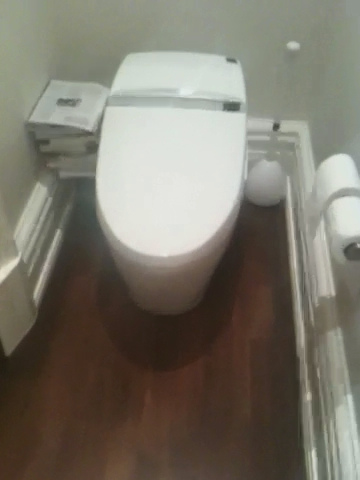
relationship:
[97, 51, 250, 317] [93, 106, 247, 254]
toliet has a lid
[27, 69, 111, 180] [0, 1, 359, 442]
newspaper on wall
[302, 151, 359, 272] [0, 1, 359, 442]
toliet paper on wall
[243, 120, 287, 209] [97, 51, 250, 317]
toilet bowl cleaner next to toliet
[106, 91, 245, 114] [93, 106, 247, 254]
stripe on lid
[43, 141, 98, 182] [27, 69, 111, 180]
books under newspaper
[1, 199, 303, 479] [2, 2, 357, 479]
floor in bathroom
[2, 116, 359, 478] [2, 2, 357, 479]
border in bathroom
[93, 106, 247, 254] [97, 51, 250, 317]
lid on toliet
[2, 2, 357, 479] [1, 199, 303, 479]
bathroom has a floor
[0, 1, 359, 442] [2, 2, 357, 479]
wall in bathroom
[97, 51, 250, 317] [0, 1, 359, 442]
toliet against wall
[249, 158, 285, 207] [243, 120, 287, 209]
base of toilet bowl cleaner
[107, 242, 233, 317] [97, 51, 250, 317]
bottom of toliet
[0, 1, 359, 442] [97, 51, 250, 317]
wall around toliet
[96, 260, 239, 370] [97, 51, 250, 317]
shadow of toliet